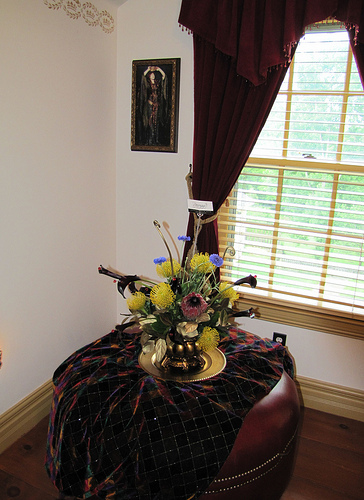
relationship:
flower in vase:
[148, 284, 181, 311] [158, 320, 211, 373]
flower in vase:
[178, 292, 206, 317] [158, 320, 211, 373]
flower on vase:
[209, 251, 225, 271] [158, 320, 211, 373]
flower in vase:
[209, 251, 225, 271] [158, 320, 211, 373]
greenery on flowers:
[141, 275, 229, 336] [122, 259, 246, 326]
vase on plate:
[158, 320, 211, 373] [136, 340, 225, 383]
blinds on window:
[211, 24, 362, 313] [183, 4, 363, 341]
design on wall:
[39, 0, 120, 36] [0, 0, 361, 397]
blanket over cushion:
[52, 325, 286, 499] [45, 326, 304, 499]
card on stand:
[188, 197, 214, 213] [175, 195, 220, 277]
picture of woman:
[129, 61, 182, 153] [140, 65, 170, 147]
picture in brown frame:
[129, 61, 182, 153] [131, 59, 179, 150]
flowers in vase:
[122, 259, 246, 326] [158, 320, 211, 373]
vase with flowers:
[158, 320, 211, 373] [122, 259, 246, 326]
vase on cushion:
[158, 320, 211, 373] [45, 326, 304, 499]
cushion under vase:
[45, 326, 304, 499] [158, 320, 211, 373]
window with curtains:
[183, 4, 363, 341] [180, 2, 363, 297]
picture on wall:
[129, 61, 182, 153] [0, 0, 361, 397]